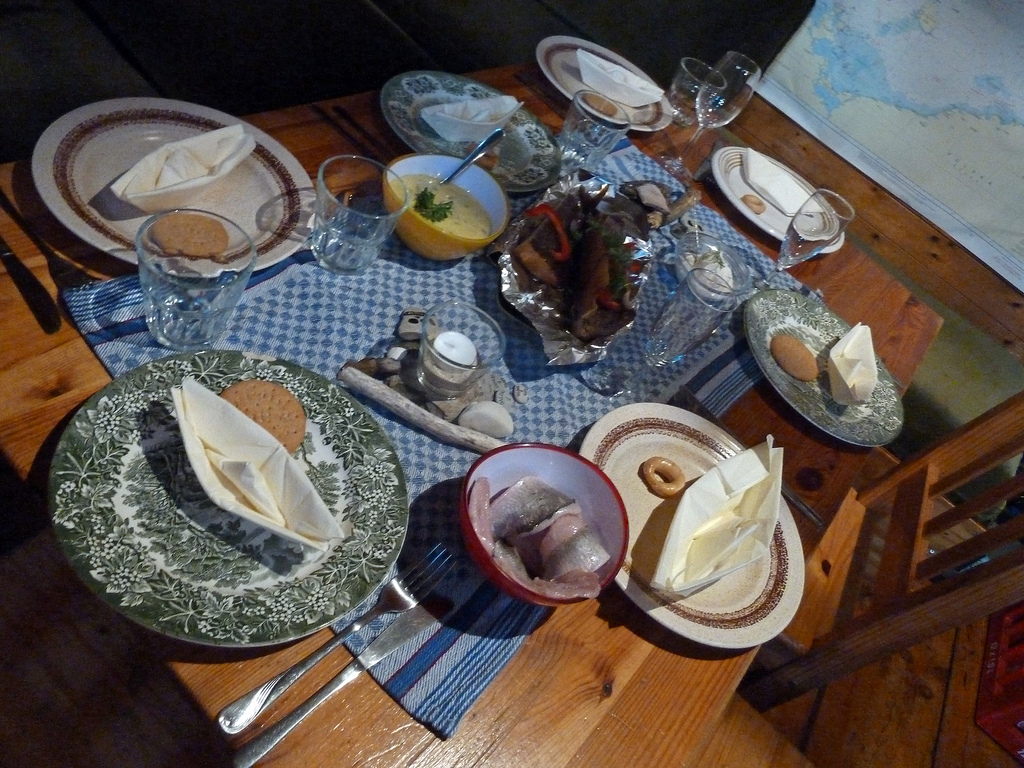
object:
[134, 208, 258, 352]
glass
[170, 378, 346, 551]
napkin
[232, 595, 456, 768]
knife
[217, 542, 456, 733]
fork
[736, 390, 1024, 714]
chair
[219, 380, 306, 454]
cookie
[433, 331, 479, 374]
candle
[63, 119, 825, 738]
table runner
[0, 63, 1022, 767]
table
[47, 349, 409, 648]
plate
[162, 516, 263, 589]
design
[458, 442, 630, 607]
red bowl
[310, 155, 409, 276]
glass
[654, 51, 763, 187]
glasses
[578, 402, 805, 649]
plate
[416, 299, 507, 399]
glass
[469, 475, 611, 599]
food